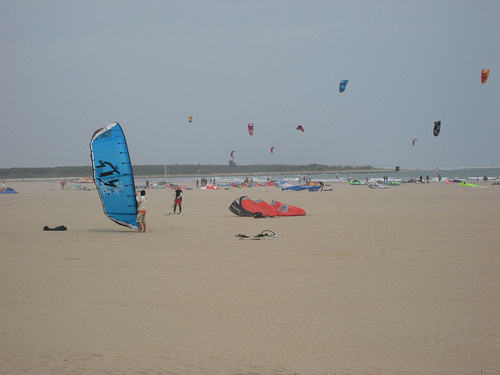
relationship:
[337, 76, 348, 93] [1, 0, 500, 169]
kite in sky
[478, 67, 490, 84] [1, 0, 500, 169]
kite in sky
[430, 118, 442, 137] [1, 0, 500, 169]
kite in sky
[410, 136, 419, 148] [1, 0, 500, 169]
kite in sky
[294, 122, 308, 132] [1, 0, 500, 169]
kite in sky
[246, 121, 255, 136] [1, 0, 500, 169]
kite in sky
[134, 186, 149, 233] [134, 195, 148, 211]
person wearing shirt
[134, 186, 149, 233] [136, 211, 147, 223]
person wearing shorts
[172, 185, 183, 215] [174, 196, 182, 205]
person wearing shorts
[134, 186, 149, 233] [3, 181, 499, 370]
person on beach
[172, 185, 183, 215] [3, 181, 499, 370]
person on beach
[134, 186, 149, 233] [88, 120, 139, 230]
person holding kite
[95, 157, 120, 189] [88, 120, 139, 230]
design on kite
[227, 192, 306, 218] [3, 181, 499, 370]
kite on beach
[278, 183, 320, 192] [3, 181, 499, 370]
kite on beach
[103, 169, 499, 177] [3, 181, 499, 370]
bay beyond beach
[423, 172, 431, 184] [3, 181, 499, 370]
person on beach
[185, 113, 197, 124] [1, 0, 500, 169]
kite in sky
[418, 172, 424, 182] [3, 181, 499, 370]
person on beach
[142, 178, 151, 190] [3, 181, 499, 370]
person on beach